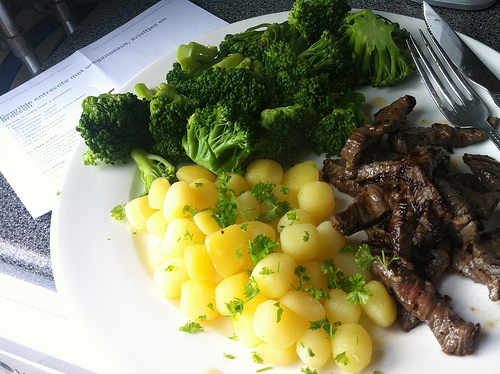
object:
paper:
[0, 0, 232, 219]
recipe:
[0, 0, 230, 219]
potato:
[253, 298, 307, 347]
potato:
[277, 220, 320, 256]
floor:
[0, 1, 99, 96]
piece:
[178, 102, 253, 177]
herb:
[247, 234, 280, 264]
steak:
[330, 185, 389, 236]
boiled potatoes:
[250, 253, 298, 300]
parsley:
[340, 273, 372, 305]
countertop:
[0, 0, 499, 292]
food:
[279, 221, 318, 261]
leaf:
[179, 321, 204, 333]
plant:
[77, 91, 155, 168]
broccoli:
[183, 103, 250, 178]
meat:
[373, 258, 479, 357]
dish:
[80, 91, 148, 166]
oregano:
[357, 279, 399, 327]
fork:
[404, 26, 499, 153]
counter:
[0, 0, 499, 288]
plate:
[47, 7, 499, 372]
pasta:
[329, 324, 372, 373]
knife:
[419, 0, 499, 109]